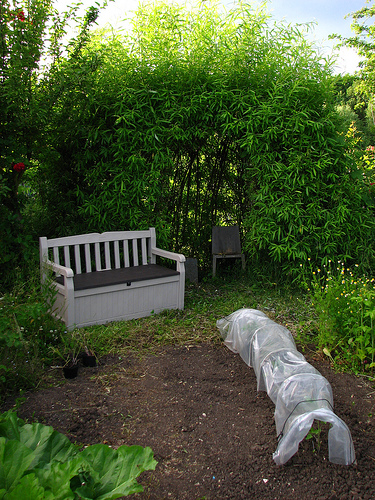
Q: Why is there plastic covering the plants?
A: To protect from pestilence.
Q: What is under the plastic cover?
A: Green plants.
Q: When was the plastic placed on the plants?
A: Before a storm.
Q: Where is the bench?
A: In the front of green trees.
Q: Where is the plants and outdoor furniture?
A: Backyard.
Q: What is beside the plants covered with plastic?
A: Flowers on a plant.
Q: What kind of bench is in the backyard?
A: Wooden.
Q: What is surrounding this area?
A: Trees.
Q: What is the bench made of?
A: Wood.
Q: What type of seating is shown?
A: Bench and chair.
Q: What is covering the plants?
A: Plastic.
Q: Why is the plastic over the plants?
A: Protecting plants.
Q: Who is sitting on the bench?
A: Nobody.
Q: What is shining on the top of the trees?
A: Sunlight.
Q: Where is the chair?
A: In the alcove of trees.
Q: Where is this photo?
A: Garden.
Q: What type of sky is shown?
A: Blue and cloudy.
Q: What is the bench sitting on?
A: Ground.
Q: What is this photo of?
A: A yard.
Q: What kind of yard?
A: A backyard.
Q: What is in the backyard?
A: A garden.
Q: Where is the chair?
A: Side of bench.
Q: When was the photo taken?
A: Daytime.